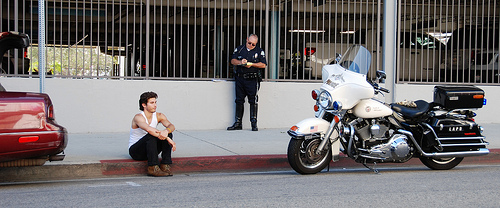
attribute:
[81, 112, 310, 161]
sidewalk — paved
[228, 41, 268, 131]
uniform — blue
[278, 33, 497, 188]
motorcycle — parked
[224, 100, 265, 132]
boots — black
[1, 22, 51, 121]
trunk — open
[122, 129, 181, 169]
pants — black, balck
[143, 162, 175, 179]
shoes — brown